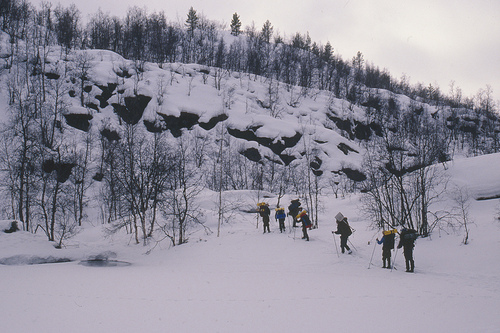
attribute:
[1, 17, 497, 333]
place — white, bright white, taken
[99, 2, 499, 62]
sky — white, blue, gray, grey, cloudy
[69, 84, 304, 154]
rocks — dark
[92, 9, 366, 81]
trees — dry, thin, deep brown, several, bare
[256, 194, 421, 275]
people — hiking, walking, close together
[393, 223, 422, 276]
man — all black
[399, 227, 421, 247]
bag — big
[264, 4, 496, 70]
clouds — white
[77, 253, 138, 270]
water — small, pooled, round